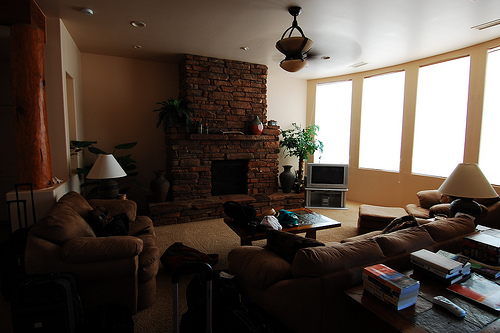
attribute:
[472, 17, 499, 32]
vent — air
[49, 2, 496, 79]
ceiling — white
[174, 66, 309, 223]
brick — red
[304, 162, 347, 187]
tv — off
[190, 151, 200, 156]
brick — red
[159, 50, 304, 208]
fireplace — dark brown, brick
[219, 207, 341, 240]
coffee table — wood-edged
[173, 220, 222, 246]
carpet — brown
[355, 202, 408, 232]
ottoman — tan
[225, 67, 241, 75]
brick — red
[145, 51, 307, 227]
fireplace — brown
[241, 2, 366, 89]
ceiling fan — running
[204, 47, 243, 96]
brick — red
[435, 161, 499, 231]
lamp — table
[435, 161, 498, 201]
shade — white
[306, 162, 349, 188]
tv — grey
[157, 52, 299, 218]
fireplace — stone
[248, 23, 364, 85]
fan blades — running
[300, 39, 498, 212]
frame — cream-colored